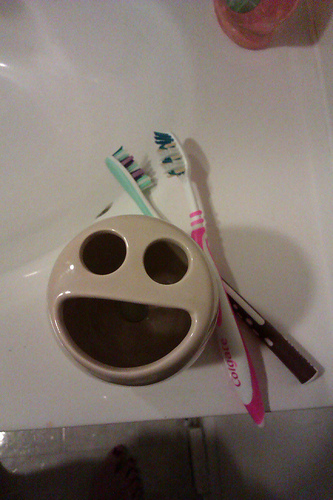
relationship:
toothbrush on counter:
[151, 120, 267, 429] [9, 51, 328, 420]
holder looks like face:
[46, 213, 221, 387] [56, 228, 192, 369]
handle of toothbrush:
[184, 177, 266, 429] [151, 120, 265, 427]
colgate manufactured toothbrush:
[220, 337, 243, 390] [151, 120, 265, 427]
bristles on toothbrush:
[152, 128, 188, 180] [151, 120, 265, 427]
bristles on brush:
[108, 143, 154, 193] [102, 138, 323, 385]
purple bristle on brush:
[113, 145, 155, 192] [102, 138, 323, 385]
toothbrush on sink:
[151, 120, 267, 429] [15, 48, 325, 421]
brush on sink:
[97, 138, 323, 386] [15, 48, 325, 421]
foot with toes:
[83, 443, 141, 499] [104, 443, 143, 488]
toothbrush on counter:
[151, 120, 265, 427] [1, 0, 332, 436]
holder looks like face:
[46, 213, 221, 387] [47, 213, 214, 377]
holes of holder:
[57, 190, 215, 289] [17, 223, 205, 374]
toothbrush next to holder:
[151, 120, 265, 427] [46, 213, 221, 387]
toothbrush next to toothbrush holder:
[151, 120, 265, 427] [45, 213, 221, 388]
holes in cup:
[78, 225, 129, 277] [43, 209, 215, 392]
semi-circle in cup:
[54, 293, 194, 373] [43, 209, 215, 392]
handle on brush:
[184, 176, 265, 429] [152, 125, 187, 180]